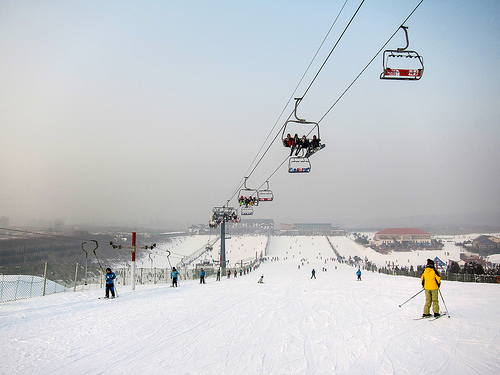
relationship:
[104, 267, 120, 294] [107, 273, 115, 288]
skier in coat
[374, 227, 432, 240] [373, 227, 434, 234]
building with roof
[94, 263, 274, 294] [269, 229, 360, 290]
skiers working up hill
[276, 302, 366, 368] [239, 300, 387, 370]
area of snow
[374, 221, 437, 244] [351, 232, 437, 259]
building with trees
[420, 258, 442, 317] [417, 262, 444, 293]
person has parka